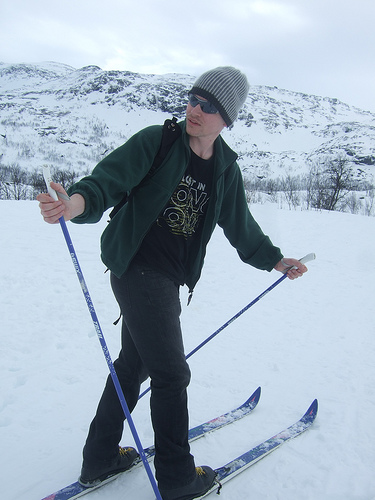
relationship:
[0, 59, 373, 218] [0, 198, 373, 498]
mountains near area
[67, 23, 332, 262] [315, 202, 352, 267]
man skiing on snow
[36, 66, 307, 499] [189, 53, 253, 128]
man wearing cap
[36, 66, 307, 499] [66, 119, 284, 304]
man wearing jacket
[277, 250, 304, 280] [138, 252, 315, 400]
hand holding ski pole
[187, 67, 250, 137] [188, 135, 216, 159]
head and neck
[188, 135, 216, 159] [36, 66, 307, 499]
neck of man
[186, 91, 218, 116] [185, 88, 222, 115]
sunglasses on eyes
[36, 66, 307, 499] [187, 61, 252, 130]
man wearing cap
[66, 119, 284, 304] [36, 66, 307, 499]
jacket of man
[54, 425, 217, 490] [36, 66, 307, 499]
boots on man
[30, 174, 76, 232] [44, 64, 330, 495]
hand of skier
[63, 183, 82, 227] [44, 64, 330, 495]
wrist of skier